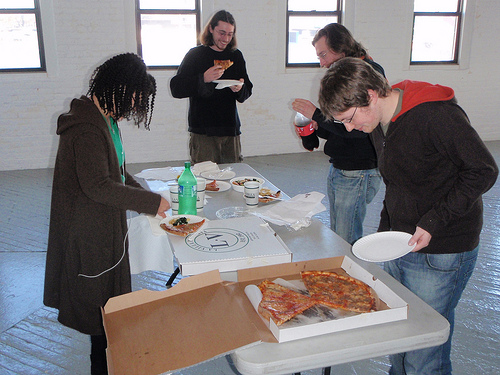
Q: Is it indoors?
A: Yes, it is indoors.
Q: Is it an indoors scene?
A: Yes, it is indoors.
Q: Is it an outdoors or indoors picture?
A: It is indoors.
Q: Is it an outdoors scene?
A: No, it is indoors.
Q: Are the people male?
A: No, they are both male and female.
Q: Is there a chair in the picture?
A: No, there are no chairs.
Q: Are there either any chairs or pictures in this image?
A: No, there are no chairs or pictures.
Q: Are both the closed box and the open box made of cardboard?
A: Yes, both the box and the box are made of cardboard.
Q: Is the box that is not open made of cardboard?
A: Yes, the box is made of cardboard.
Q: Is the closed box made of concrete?
A: No, the box is made of cardboard.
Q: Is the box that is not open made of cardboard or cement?
A: The box is made of cardboard.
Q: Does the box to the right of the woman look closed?
A: Yes, the box is closed.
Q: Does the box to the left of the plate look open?
A: No, the box is closed.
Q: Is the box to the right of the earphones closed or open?
A: The box is closed.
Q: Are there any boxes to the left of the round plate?
A: Yes, there is a box to the left of the plate.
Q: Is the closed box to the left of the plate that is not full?
A: Yes, the box is to the left of the plate.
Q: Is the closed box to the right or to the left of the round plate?
A: The box is to the left of the plate.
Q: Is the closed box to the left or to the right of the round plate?
A: The box is to the left of the plate.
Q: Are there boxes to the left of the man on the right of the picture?
A: Yes, there is a box to the left of the man.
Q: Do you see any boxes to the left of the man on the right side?
A: Yes, there is a box to the left of the man.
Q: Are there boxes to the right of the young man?
A: No, the box is to the left of the man.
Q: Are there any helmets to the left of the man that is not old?
A: No, there is a box to the left of the man.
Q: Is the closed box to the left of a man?
A: Yes, the box is to the left of a man.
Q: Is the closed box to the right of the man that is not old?
A: No, the box is to the left of the man.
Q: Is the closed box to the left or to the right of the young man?
A: The box is to the left of the man.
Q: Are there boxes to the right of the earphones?
A: Yes, there is a box to the right of the earphones.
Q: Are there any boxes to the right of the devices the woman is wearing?
A: Yes, there is a box to the right of the earphones.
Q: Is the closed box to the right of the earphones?
A: Yes, the box is to the right of the earphones.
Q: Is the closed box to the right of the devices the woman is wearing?
A: Yes, the box is to the right of the earphones.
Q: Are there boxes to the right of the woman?
A: Yes, there is a box to the right of the woman.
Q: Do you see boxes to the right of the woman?
A: Yes, there is a box to the right of the woman.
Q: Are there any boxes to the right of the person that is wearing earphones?
A: Yes, there is a box to the right of the woman.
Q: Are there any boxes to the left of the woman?
A: No, the box is to the right of the woman.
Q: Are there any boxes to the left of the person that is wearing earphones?
A: No, the box is to the right of the woman.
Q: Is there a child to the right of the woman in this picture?
A: No, there is a box to the right of the woman.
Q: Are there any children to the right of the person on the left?
A: No, there is a box to the right of the woman.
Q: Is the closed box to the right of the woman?
A: Yes, the box is to the right of the woman.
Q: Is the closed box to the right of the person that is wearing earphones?
A: Yes, the box is to the right of the woman.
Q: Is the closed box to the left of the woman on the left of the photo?
A: No, the box is to the right of the woman.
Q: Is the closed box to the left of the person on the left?
A: No, the box is to the right of the woman.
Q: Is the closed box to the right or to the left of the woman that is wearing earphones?
A: The box is to the right of the woman.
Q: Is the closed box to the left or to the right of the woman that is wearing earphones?
A: The box is to the right of the woman.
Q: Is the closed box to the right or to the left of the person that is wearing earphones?
A: The box is to the right of the woman.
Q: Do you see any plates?
A: Yes, there is a plate.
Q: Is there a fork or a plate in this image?
A: Yes, there is a plate.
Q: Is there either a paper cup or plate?
A: Yes, there is a paper plate.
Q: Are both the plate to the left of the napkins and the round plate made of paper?
A: Yes, both the plate and the plate are made of paper.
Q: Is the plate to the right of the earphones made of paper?
A: Yes, the plate is made of paper.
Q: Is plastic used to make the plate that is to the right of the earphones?
A: No, the plate is made of paper.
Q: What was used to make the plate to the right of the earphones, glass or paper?
A: The plate is made of paper.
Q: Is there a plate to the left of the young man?
A: Yes, there is a plate to the left of the man.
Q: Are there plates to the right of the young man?
A: No, the plate is to the left of the man.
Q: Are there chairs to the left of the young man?
A: No, there is a plate to the left of the man.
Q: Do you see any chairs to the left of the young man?
A: No, there is a plate to the left of the man.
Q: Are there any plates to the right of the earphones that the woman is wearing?
A: Yes, there is a plate to the right of the earphones.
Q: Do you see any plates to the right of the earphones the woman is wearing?
A: Yes, there is a plate to the right of the earphones.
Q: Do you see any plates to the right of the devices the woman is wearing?
A: Yes, there is a plate to the right of the earphones.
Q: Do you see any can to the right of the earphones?
A: No, there is a plate to the right of the earphones.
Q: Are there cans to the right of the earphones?
A: No, there is a plate to the right of the earphones.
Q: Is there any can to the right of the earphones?
A: No, there is a plate to the right of the earphones.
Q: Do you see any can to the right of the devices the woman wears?
A: No, there is a plate to the right of the earphones.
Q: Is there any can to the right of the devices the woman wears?
A: No, there is a plate to the right of the earphones.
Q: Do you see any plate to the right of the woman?
A: Yes, there is a plate to the right of the woman.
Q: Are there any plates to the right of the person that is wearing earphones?
A: Yes, there is a plate to the right of the woman.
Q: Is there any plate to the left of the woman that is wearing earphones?
A: No, the plate is to the right of the woman.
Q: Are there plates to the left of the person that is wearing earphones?
A: No, the plate is to the right of the woman.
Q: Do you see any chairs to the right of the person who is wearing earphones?
A: No, there is a plate to the right of the woman.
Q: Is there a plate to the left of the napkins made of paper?
A: Yes, there is a plate to the left of the napkins.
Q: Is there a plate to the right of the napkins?
A: No, the plate is to the left of the napkins.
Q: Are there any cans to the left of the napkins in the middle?
A: No, there is a plate to the left of the napkins.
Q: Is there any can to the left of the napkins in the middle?
A: No, there is a plate to the left of the napkins.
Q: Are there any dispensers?
A: No, there are no dispensers.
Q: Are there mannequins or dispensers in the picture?
A: No, there are no dispensers or mannequins.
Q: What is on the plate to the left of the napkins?
A: The pizza slice is on the plate.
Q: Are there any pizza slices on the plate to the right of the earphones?
A: Yes, there is a pizza slice on the plate.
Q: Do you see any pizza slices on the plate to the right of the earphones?
A: Yes, there is a pizza slice on the plate.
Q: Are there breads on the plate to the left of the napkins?
A: No, there is a pizza slice on the plate.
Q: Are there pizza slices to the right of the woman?
A: Yes, there is a pizza slice to the right of the woman.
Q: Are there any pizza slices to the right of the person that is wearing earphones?
A: Yes, there is a pizza slice to the right of the woman.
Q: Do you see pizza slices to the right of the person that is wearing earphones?
A: Yes, there is a pizza slice to the right of the woman.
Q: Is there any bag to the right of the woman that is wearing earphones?
A: No, there is a pizza slice to the right of the woman.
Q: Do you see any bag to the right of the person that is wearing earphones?
A: No, there is a pizza slice to the right of the woman.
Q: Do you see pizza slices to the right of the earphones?
A: Yes, there is a pizza slice to the right of the earphones.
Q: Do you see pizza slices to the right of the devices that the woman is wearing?
A: Yes, there is a pizza slice to the right of the earphones.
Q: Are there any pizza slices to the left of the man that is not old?
A: Yes, there is a pizza slice to the left of the man.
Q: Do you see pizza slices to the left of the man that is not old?
A: Yes, there is a pizza slice to the left of the man.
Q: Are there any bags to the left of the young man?
A: No, there is a pizza slice to the left of the man.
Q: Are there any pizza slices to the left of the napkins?
A: Yes, there is a pizza slice to the left of the napkins.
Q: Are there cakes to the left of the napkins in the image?
A: No, there is a pizza slice to the left of the napkins.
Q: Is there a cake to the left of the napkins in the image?
A: No, there is a pizza slice to the left of the napkins.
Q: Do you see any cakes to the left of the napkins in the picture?
A: No, there is a pizza slice to the left of the napkins.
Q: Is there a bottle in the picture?
A: Yes, there is a bottle.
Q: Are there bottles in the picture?
A: Yes, there is a bottle.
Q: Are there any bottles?
A: Yes, there is a bottle.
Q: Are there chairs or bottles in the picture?
A: Yes, there is a bottle.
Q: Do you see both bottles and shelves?
A: No, there is a bottle but no shelves.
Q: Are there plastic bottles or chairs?
A: Yes, there is a plastic bottle.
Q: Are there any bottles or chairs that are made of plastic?
A: Yes, the bottle is made of plastic.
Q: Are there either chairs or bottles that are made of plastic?
A: Yes, the bottle is made of plastic.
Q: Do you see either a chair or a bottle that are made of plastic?
A: Yes, the bottle is made of plastic.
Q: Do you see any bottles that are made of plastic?
A: Yes, there is a bottle that is made of plastic.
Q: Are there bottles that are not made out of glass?
A: Yes, there is a bottle that is made of plastic.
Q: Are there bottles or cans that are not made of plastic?
A: No, there is a bottle but it is made of plastic.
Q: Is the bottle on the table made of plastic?
A: Yes, the bottle is made of plastic.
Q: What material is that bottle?
A: The bottle is made of plastic.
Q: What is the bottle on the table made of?
A: The bottle is made of plastic.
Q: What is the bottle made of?
A: The bottle is made of plastic.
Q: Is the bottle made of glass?
A: No, the bottle is made of plastic.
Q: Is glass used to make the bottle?
A: No, the bottle is made of plastic.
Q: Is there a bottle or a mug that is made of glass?
A: No, there is a bottle but it is made of plastic.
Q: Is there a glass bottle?
A: No, there is a bottle but it is made of plastic.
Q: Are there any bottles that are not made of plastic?
A: No, there is a bottle but it is made of plastic.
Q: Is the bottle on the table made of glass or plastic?
A: The bottle is made of plastic.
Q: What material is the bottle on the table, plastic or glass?
A: The bottle is made of plastic.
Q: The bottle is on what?
A: The bottle is on the table.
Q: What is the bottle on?
A: The bottle is on the table.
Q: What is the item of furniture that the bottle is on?
A: The piece of furniture is a table.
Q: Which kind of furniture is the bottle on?
A: The bottle is on the table.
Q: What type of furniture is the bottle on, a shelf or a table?
A: The bottle is on a table.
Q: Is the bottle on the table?
A: Yes, the bottle is on the table.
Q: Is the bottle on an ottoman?
A: No, the bottle is on the table.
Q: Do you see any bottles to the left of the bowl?
A: Yes, there is a bottle to the left of the bowl.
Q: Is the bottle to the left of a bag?
A: No, the bottle is to the left of the bowl.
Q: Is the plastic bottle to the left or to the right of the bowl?
A: The bottle is to the left of the bowl.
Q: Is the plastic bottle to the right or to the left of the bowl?
A: The bottle is to the left of the bowl.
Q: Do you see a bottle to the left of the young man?
A: Yes, there is a bottle to the left of the man.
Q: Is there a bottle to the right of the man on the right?
A: No, the bottle is to the left of the man.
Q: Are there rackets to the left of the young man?
A: No, there is a bottle to the left of the man.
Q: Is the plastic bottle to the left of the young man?
A: Yes, the bottle is to the left of the man.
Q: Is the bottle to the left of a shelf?
A: No, the bottle is to the left of the man.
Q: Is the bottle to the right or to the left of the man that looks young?
A: The bottle is to the left of the man.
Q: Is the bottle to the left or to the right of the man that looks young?
A: The bottle is to the left of the man.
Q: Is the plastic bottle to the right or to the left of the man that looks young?
A: The bottle is to the left of the man.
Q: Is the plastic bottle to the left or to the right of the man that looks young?
A: The bottle is to the left of the man.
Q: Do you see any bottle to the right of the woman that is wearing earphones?
A: Yes, there is a bottle to the right of the woman.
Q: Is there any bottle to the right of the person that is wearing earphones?
A: Yes, there is a bottle to the right of the woman.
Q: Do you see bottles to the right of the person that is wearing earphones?
A: Yes, there is a bottle to the right of the woman.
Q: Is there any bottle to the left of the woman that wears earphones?
A: No, the bottle is to the right of the woman.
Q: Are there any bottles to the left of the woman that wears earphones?
A: No, the bottle is to the right of the woman.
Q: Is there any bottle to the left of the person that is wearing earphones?
A: No, the bottle is to the right of the woman.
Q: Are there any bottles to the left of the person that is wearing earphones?
A: No, the bottle is to the right of the woman.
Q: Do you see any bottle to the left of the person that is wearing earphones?
A: No, the bottle is to the right of the woman.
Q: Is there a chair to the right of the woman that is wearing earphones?
A: No, there is a bottle to the right of the woman.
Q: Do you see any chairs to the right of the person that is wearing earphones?
A: No, there is a bottle to the right of the woman.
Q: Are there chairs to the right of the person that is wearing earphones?
A: No, there is a bottle to the right of the woman.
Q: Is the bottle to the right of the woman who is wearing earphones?
A: Yes, the bottle is to the right of the woman.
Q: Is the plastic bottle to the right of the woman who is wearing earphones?
A: Yes, the bottle is to the right of the woman.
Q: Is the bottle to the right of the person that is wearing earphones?
A: Yes, the bottle is to the right of the woman.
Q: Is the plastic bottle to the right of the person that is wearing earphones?
A: Yes, the bottle is to the right of the woman.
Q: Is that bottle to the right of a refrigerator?
A: No, the bottle is to the right of the woman.